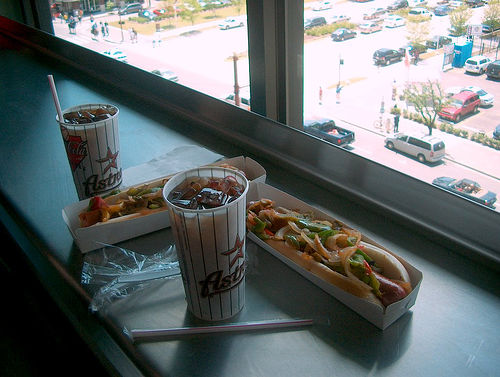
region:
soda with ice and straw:
[31, 73, 129, 195]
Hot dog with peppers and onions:
[247, 184, 433, 317]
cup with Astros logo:
[163, 171, 256, 316]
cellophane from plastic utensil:
[74, 242, 186, 308]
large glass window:
[296, 5, 493, 216]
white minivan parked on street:
[382, 130, 460, 164]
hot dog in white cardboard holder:
[249, 177, 443, 331]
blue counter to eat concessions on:
[6, 208, 494, 371]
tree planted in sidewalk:
[404, 80, 457, 132]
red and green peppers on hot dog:
[249, 200, 391, 302]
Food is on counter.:
[58, 98, 428, 353]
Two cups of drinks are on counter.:
[51, 98, 263, 308]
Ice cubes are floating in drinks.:
[157, 166, 247, 232]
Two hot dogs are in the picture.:
[78, 145, 402, 321]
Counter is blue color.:
[283, 324, 391, 374]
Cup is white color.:
[55, 147, 248, 306]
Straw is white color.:
[125, 316, 336, 351]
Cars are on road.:
[308, 4, 489, 181]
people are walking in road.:
[310, 65, 411, 137]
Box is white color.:
[59, 204, 413, 335]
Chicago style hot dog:
[249, 179, 426, 331]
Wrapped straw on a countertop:
[118, 311, 320, 342]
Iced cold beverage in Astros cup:
[160, 159, 251, 322]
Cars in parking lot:
[309, 28, 499, 207]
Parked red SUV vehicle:
[436, 88, 483, 125]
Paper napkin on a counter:
[121, 139, 225, 184]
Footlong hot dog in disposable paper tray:
[251, 176, 428, 328]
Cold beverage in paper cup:
[43, 65, 133, 202]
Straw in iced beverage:
[46, 70, 132, 197]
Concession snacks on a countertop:
[3, 64, 443, 352]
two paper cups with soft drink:
[51, 92, 271, 327]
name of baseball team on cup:
[199, 238, 247, 299]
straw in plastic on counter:
[124, 311, 321, 350]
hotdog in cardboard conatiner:
[260, 180, 429, 335]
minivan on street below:
[376, 122, 451, 168]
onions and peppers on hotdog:
[285, 203, 357, 269]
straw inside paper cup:
[40, 66, 77, 138]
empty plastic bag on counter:
[78, 243, 164, 315]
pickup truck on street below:
[300, 114, 356, 146]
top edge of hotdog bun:
[365, 239, 401, 275]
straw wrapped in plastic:
[119, 312, 331, 347]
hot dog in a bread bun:
[250, 190, 417, 318]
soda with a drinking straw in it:
[43, 72, 127, 207]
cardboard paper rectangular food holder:
[213, 177, 426, 330]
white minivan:
[381, 122, 448, 164]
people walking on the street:
[49, 5, 141, 46]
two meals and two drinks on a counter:
[28, 69, 427, 350]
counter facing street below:
[0, 44, 499, 374]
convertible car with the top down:
[428, 170, 498, 207]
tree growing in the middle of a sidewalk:
[401, 75, 446, 145]